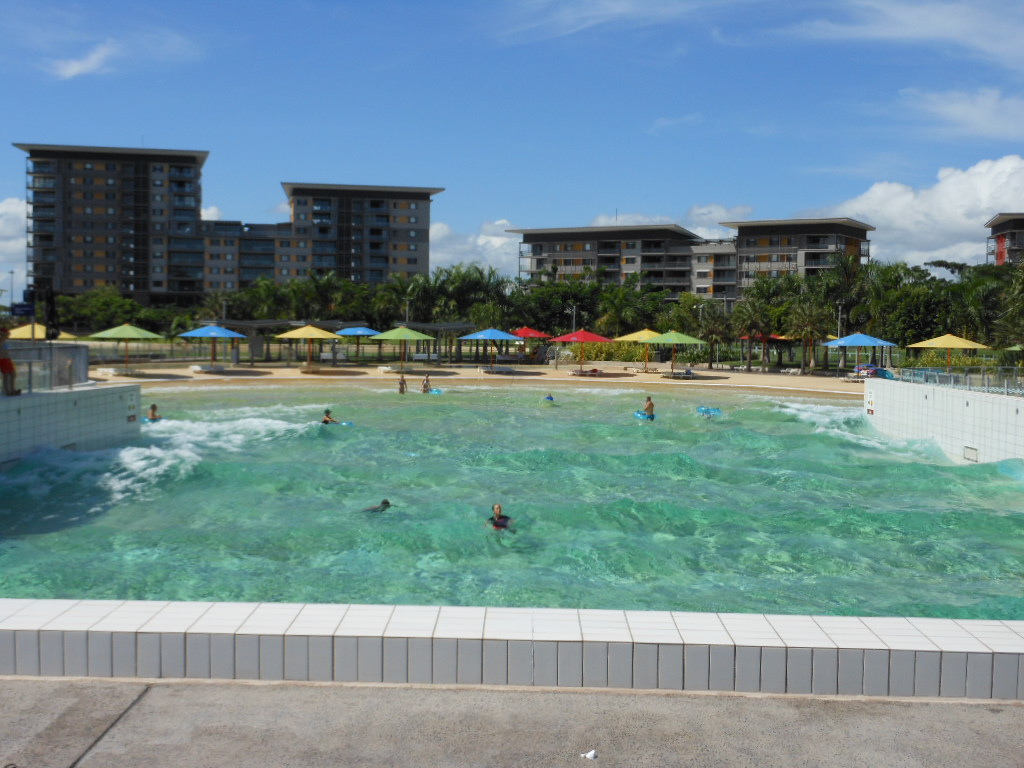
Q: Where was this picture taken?
A: Close to pool.